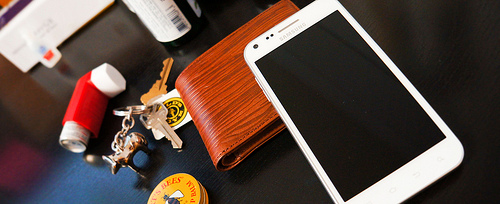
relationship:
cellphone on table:
[244, 2, 464, 204] [0, 2, 499, 204]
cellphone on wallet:
[244, 2, 464, 204] [175, 2, 300, 171]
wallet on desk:
[175, 2, 300, 171] [0, 2, 499, 204]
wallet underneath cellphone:
[175, 2, 300, 171] [244, 2, 464, 204]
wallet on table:
[175, 2, 300, 171] [0, 2, 499, 204]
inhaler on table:
[57, 63, 127, 155] [0, 2, 499, 204]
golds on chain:
[134, 101, 186, 150] [102, 103, 151, 176]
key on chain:
[137, 56, 173, 108] [102, 103, 151, 176]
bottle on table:
[123, 0, 210, 51] [0, 2, 499, 204]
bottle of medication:
[123, 0, 210, 51] [123, 0, 208, 52]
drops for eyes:
[16, 23, 62, 68] [19, 26, 62, 70]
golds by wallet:
[134, 101, 186, 150] [175, 2, 300, 171]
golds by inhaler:
[134, 101, 186, 150] [57, 63, 127, 155]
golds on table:
[134, 101, 186, 150] [0, 2, 499, 204]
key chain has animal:
[102, 103, 151, 176] [99, 131, 152, 180]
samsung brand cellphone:
[273, 16, 313, 46] [244, 2, 464, 204]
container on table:
[143, 172, 217, 202] [0, 2, 499, 204]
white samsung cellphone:
[244, 2, 464, 204] [244, 2, 464, 204]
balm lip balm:
[140, 172, 216, 203] [144, 172, 210, 202]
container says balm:
[143, 172, 217, 202] [140, 172, 216, 203]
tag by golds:
[147, 88, 197, 141] [134, 101, 186, 150]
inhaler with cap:
[57, 63, 127, 155] [90, 61, 128, 97]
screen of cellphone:
[254, 9, 447, 201] [244, 2, 464, 204]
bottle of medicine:
[123, 0, 210, 51] [123, 0, 208, 52]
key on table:
[137, 56, 173, 108] [0, 2, 499, 204]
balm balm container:
[140, 172, 216, 203] [143, 172, 217, 202]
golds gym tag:
[141, 90, 195, 142] [147, 88, 197, 141]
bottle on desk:
[123, 0, 210, 51] [0, 2, 499, 204]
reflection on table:
[1, 136, 46, 199] [0, 2, 499, 204]